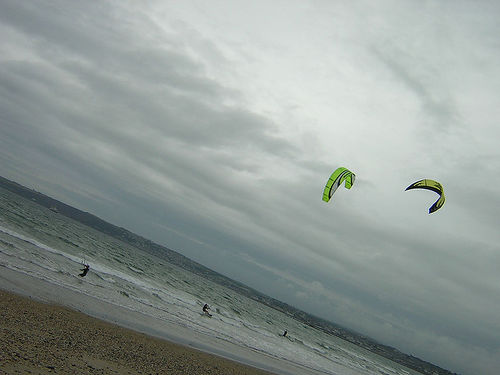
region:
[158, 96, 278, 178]
Clouds in the skies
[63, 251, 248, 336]
People surfing in the ocean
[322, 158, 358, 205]
green kite in the sky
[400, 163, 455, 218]
yellow kite in the sky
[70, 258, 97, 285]
person standing in the water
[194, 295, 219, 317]
person parasailing in the water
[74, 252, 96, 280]
person sailing in the water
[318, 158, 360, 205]
green white and black kite in the sky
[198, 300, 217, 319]
person para sailing in the ocean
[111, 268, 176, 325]
water washing up ashore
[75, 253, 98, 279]
person standing in the water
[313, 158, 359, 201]
this is a kite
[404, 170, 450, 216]
this is a kite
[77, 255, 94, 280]
this is a person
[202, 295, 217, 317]
this is a person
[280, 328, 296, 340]
this is a person's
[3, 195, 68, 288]
this is a body of water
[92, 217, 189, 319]
this is a body of water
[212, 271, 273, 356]
this is a body of water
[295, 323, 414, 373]
this is a body of water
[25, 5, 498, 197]
this is the sky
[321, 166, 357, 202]
The green parasail on the left.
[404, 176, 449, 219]
The yellow and black parasail on the right.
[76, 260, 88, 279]
The person on the left in the water.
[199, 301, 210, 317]
The person in the middle in the water.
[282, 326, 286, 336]
The person in the water on the right.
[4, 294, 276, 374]
The sand on the beach.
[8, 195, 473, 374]
The water of the beach.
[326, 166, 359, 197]
The black design on the green parasail.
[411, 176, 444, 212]
The black design on the yellow and black parasail.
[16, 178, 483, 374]
The water in the distance.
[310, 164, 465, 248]
two kites in sky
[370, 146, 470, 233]
blue and yellow kite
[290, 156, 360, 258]
green and red kite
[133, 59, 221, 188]
grey and white sky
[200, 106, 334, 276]
heavy clouds in sky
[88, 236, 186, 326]
white waves on water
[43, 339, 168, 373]
brown sand near water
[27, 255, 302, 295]
people wading in water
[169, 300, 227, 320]
person riding on board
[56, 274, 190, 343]
water washes onto shore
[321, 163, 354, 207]
A green kite in the sky.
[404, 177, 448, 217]
A large kite in the sky.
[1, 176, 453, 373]
The beach under a gray sky.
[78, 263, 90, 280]
A person on water.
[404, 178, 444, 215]
a large green surf kite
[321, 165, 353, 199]
a large green surf kite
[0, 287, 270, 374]
a brown sandy beach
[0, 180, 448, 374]
the ocean and a sandy beach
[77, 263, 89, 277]
person in the water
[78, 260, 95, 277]
A person is playing.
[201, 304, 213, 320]
A person is playing.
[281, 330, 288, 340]
A person is playing.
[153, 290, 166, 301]
A wave in the water.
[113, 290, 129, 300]
A wave in the water.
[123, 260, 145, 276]
A wave in the water.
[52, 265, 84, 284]
A wave in the water.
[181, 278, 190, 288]
A wave in the water.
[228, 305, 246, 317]
A wave in the water.